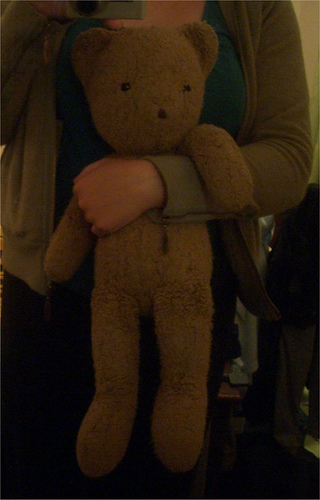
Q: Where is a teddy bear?
A: In a person's arms.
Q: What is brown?
A: Teddy bear.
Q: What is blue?
A: Person's shirt.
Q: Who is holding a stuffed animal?
A: A person.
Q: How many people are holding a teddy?
A: One.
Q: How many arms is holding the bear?
A: Only one.